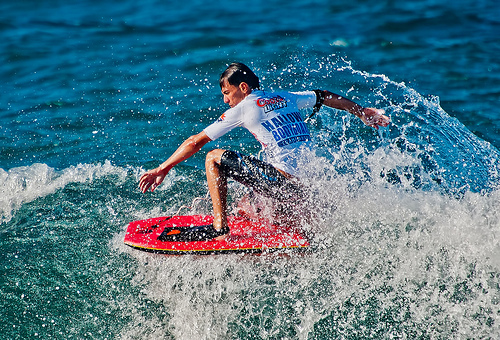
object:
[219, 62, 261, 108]
head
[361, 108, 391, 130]
hand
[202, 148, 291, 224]
leg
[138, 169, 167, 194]
hand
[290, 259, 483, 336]
wave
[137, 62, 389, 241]
man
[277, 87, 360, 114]
arm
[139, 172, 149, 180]
finger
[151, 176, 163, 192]
finger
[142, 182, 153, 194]
finger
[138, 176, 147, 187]
finger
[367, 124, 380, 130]
finger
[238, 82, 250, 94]
ear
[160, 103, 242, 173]
arm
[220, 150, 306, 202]
shorts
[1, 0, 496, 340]
sea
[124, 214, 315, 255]
surfboard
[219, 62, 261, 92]
wet hair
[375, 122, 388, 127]
finger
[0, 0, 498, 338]
photo